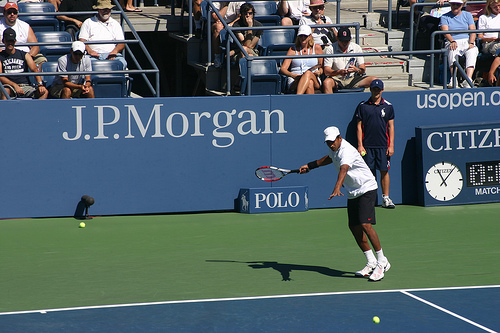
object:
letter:
[188, 110, 212, 139]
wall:
[0, 87, 500, 220]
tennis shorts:
[345, 190, 379, 228]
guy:
[298, 124, 392, 283]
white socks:
[375, 247, 387, 263]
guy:
[353, 79, 396, 210]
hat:
[370, 79, 385, 88]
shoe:
[367, 259, 394, 281]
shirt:
[325, 138, 380, 200]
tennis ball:
[369, 315, 383, 325]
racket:
[253, 164, 306, 183]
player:
[297, 125, 392, 283]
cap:
[323, 125, 341, 145]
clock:
[422, 159, 465, 204]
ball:
[77, 219, 88, 228]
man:
[76, 0, 134, 77]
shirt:
[77, 14, 129, 55]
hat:
[92, 0, 120, 9]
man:
[354, 77, 398, 209]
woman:
[278, 22, 328, 96]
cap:
[294, 25, 313, 39]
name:
[62, 103, 292, 150]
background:
[0, 0, 500, 331]